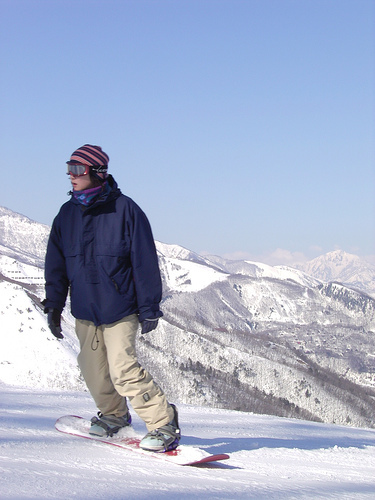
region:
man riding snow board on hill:
[29, 122, 221, 454]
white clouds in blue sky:
[34, 76, 72, 108]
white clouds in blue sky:
[236, 71, 279, 121]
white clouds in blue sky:
[202, 155, 243, 183]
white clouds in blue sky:
[259, 71, 304, 157]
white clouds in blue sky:
[166, 107, 198, 163]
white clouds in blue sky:
[215, 175, 265, 201]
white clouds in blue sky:
[135, 94, 186, 129]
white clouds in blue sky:
[79, 78, 109, 103]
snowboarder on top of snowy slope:
[42, 133, 231, 468]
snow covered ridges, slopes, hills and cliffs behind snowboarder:
[2, 200, 366, 411]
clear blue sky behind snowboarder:
[0, 2, 366, 269]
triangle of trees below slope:
[180, 360, 316, 420]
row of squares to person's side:
[1, 263, 61, 279]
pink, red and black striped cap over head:
[63, 141, 108, 177]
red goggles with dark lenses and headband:
[63, 159, 104, 174]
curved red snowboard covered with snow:
[50, 405, 224, 465]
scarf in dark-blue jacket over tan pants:
[35, 186, 173, 419]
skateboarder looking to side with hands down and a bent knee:
[38, 138, 159, 339]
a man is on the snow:
[34, 104, 225, 464]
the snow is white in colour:
[182, 256, 270, 379]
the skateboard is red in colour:
[179, 446, 239, 494]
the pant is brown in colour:
[74, 312, 183, 436]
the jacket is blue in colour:
[50, 201, 158, 326]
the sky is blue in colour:
[98, 40, 254, 121]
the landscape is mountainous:
[161, 209, 331, 406]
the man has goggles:
[55, 159, 101, 178]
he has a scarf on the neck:
[62, 184, 111, 202]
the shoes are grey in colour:
[129, 418, 184, 466]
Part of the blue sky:
[188, 57, 234, 163]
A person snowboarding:
[38, 139, 230, 467]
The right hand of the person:
[36, 302, 66, 340]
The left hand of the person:
[136, 308, 162, 334]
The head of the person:
[63, 140, 116, 193]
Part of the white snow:
[283, 451, 302, 481]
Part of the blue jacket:
[105, 225, 118, 280]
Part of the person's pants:
[111, 331, 124, 363]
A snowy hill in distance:
[303, 246, 372, 282]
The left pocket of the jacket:
[105, 269, 127, 299]